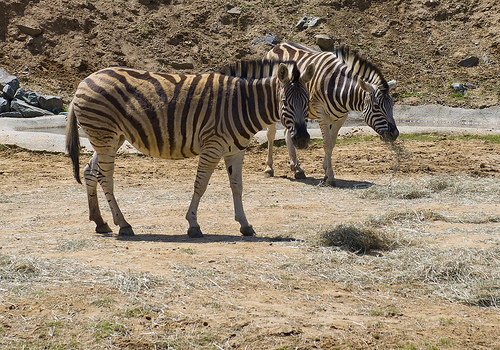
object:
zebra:
[65, 62, 317, 239]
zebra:
[263, 42, 400, 187]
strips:
[128, 78, 174, 147]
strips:
[314, 52, 342, 113]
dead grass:
[111, 270, 168, 311]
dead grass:
[350, 225, 442, 264]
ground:
[0, 119, 500, 347]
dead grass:
[9, 257, 51, 287]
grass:
[463, 277, 498, 306]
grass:
[383, 170, 480, 189]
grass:
[348, 234, 425, 348]